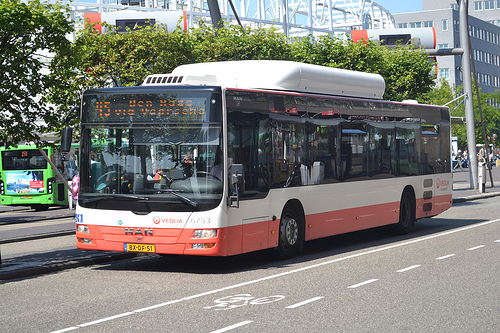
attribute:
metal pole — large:
[453, 2, 482, 188]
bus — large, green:
[15, 132, 165, 208]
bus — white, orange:
[99, 47, 469, 294]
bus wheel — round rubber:
[278, 205, 307, 255]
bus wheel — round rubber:
[274, 198, 304, 258]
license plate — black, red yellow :
[124, 239, 154, 259]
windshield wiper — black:
[96, 131, 214, 224]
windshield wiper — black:
[95, 150, 209, 206]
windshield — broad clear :
[80, 90, 218, 213]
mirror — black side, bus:
[231, 160, 244, 221]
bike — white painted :
[191, 292, 312, 316]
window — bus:
[284, 98, 409, 176]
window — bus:
[292, 108, 393, 188]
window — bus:
[288, 103, 388, 175]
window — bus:
[279, 120, 360, 177]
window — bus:
[234, 110, 288, 186]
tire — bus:
[277, 195, 324, 253]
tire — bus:
[275, 206, 307, 260]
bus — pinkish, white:
[56, 58, 454, 260]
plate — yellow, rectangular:
[121, 241, 155, 251]